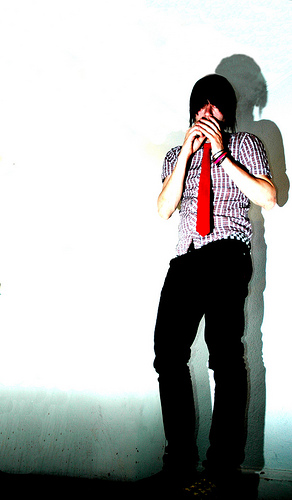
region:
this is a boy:
[152, 71, 259, 475]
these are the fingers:
[190, 116, 218, 143]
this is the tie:
[191, 159, 215, 232]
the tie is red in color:
[198, 216, 210, 223]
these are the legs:
[153, 287, 242, 488]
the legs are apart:
[177, 335, 223, 385]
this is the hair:
[199, 78, 226, 98]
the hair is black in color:
[199, 78, 226, 98]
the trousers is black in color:
[206, 262, 231, 287]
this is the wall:
[0, 255, 140, 401]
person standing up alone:
[149, 67, 290, 494]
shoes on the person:
[130, 466, 234, 499]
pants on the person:
[156, 243, 252, 462]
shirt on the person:
[159, 131, 259, 248]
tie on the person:
[192, 142, 214, 241]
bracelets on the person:
[207, 148, 229, 164]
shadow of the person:
[217, 48, 290, 497]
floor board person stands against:
[262, 467, 291, 483]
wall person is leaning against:
[14, 81, 141, 371]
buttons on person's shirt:
[192, 172, 197, 235]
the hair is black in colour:
[190, 73, 233, 99]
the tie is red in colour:
[196, 139, 216, 238]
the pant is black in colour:
[138, 252, 257, 486]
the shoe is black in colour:
[135, 463, 236, 498]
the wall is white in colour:
[26, 360, 108, 458]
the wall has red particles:
[39, 406, 137, 482]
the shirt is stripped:
[208, 184, 237, 225]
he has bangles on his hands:
[192, 144, 230, 172]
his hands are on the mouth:
[188, 108, 245, 168]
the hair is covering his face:
[179, 85, 234, 127]